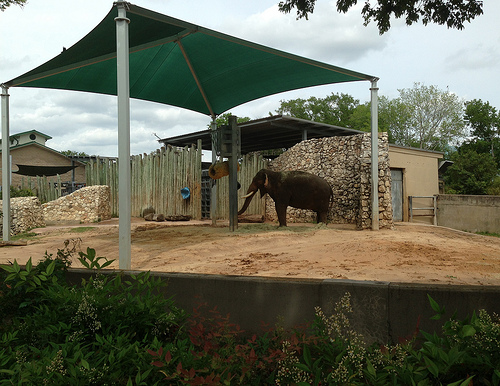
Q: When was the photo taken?
A: Daytime.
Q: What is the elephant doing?
A: Standing.